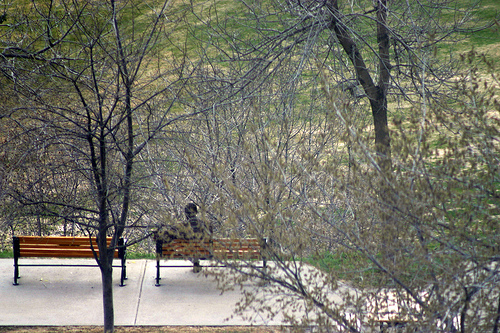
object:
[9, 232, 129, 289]
bench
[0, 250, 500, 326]
sidewalk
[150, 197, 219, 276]
man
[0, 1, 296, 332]
tree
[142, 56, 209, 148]
branch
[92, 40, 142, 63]
leaves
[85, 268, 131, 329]
stem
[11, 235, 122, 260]
back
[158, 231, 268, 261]
back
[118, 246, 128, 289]
leg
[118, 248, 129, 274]
edge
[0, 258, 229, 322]
snow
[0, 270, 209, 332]
ground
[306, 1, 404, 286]
plant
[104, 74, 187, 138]
branches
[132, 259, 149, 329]
crack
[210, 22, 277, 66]
grass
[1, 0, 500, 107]
hill